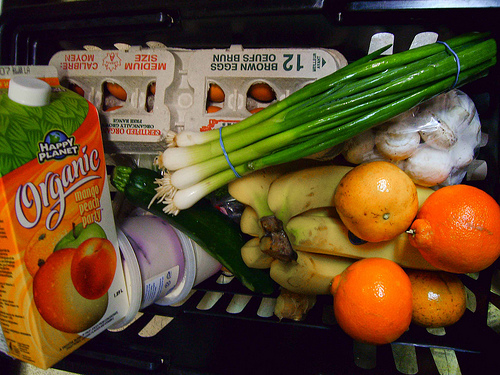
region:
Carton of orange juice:
[5, 57, 152, 345]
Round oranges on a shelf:
[321, 163, 491, 373]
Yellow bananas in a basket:
[219, 146, 426, 311]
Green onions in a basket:
[152, 70, 451, 215]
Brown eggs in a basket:
[38, 35, 322, 145]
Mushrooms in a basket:
[350, 95, 482, 181]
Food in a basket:
[56, 61, 469, 306]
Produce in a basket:
[161, 97, 491, 349]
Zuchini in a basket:
[104, 158, 316, 324]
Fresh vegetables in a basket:
[86, 87, 490, 369]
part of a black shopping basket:
[97, 263, 495, 373]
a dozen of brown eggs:
[30, 35, 347, 162]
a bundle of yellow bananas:
[227, 166, 497, 312]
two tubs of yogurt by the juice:
[95, 200, 232, 340]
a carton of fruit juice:
[0, 47, 135, 369]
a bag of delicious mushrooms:
[320, 76, 486, 207]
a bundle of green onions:
[137, 20, 497, 225]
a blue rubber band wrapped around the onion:
[210, 120, 245, 195]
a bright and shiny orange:
[317, 151, 422, 242]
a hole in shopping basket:
[219, 280, 253, 327]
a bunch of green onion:
[150, 35, 496, 211]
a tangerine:
[327, 256, 407, 341]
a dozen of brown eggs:
[45, 45, 346, 166]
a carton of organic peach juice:
[0, 56, 130, 362]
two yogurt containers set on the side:
[110, 205, 220, 326]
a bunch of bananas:
[225, 157, 452, 293]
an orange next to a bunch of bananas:
[333, 157, 414, 243]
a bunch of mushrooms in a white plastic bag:
[340, 86, 481, 186]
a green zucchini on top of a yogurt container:
[110, 162, 280, 297]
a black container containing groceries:
[1, 3, 497, 373]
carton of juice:
[1, 53, 138, 372]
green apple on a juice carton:
[51, 217, 111, 262]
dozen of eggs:
[41, 43, 358, 165]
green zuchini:
[104, 156, 277, 306]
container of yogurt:
[101, 205, 190, 332]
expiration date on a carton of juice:
[2, 62, 33, 75]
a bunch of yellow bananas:
[223, 149, 475, 314]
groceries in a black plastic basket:
[1, 15, 498, 372]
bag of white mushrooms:
[332, 80, 484, 194]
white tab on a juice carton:
[6, 73, 57, 110]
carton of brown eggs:
[34, 45, 354, 156]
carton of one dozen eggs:
[41, 41, 357, 167]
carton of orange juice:
[0, 65, 135, 370]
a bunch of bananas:
[219, 148, 419, 308]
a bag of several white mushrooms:
[328, 58, 479, 179]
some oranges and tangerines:
[326, 155, 495, 349]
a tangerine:
[402, 169, 499, 283]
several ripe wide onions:
[145, 30, 498, 221]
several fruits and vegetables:
[6, 50, 476, 367]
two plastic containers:
[101, 204, 224, 320]